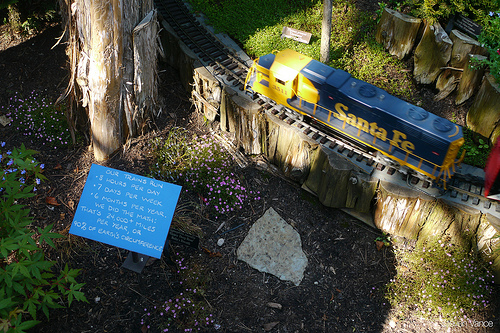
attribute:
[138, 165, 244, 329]
flowers — pink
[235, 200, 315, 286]
rock — grey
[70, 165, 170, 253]
words — written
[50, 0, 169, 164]
tree stump — small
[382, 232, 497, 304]
flowers — pink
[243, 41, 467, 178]
train — yellow, blue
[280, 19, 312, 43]
information sign — small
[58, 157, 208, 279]
sign — small, handwritten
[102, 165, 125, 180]
word — written, white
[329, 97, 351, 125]
letter — yellow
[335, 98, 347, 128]
letter — yellow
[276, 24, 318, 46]
sign — small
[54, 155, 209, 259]
sign — blue, white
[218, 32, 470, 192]
train — navy, yellow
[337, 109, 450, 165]
letter — yellow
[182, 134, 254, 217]
flowers — small, purple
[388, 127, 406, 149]
letter — yellow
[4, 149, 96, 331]
plants — green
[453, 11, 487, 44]
card — explaining